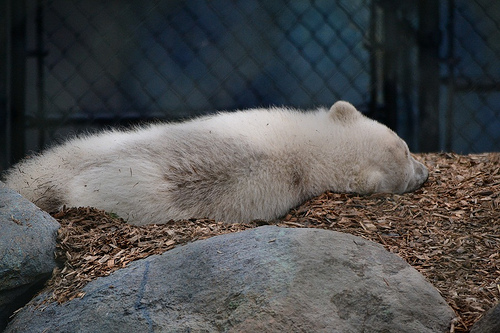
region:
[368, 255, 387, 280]
edge of a rock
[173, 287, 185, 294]
side of a rock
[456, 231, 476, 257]
part of the grass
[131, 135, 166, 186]
back of a dog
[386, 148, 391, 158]
head of a dog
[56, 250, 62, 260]
side of a rock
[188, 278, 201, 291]
part of a rock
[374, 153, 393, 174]
part of an head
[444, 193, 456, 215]
part of the surface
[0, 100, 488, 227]
A white bear lying on wood chips.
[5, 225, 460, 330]
A large stone.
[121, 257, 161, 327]
A blue mark on the stone.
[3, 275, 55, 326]
A gap between two stones.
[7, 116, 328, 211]
Bits of wood chips on the bear's fur.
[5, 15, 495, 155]
A metal fence.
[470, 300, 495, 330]
The edge of a stone.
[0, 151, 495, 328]
Wood chips spread over stones.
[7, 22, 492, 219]
A fence behind a white bear.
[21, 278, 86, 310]
Wood chips on the slope of a stone.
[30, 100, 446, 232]
a white bear asleep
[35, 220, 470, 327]
a stone by the bear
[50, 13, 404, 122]
a chain link fence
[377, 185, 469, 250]
wood chips on the ground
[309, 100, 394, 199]
ears of a white bear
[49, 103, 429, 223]
a white furry bear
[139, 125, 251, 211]
a gray spot on the fur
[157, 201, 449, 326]
a gray boulder in the pen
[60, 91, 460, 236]
a white bear a sleep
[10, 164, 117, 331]
a gray boulder on top of another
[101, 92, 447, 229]
the bear is sleeping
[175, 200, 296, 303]
a big, gray rock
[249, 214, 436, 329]
a big, gray rock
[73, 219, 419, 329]
a big, gray rock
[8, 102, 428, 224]
A bear laying down.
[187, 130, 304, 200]
Light white and grey fur.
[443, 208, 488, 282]
Woodchips on the ground.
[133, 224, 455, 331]
Large grey rock.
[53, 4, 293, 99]
A chain link fence.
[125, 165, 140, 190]
Woodchips in the fur of the bear.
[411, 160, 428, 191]
The nose of the bear.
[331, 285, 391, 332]
Dark spot on the rock.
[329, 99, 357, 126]
The ear of the bear.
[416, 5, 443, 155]
A dark metal pole.